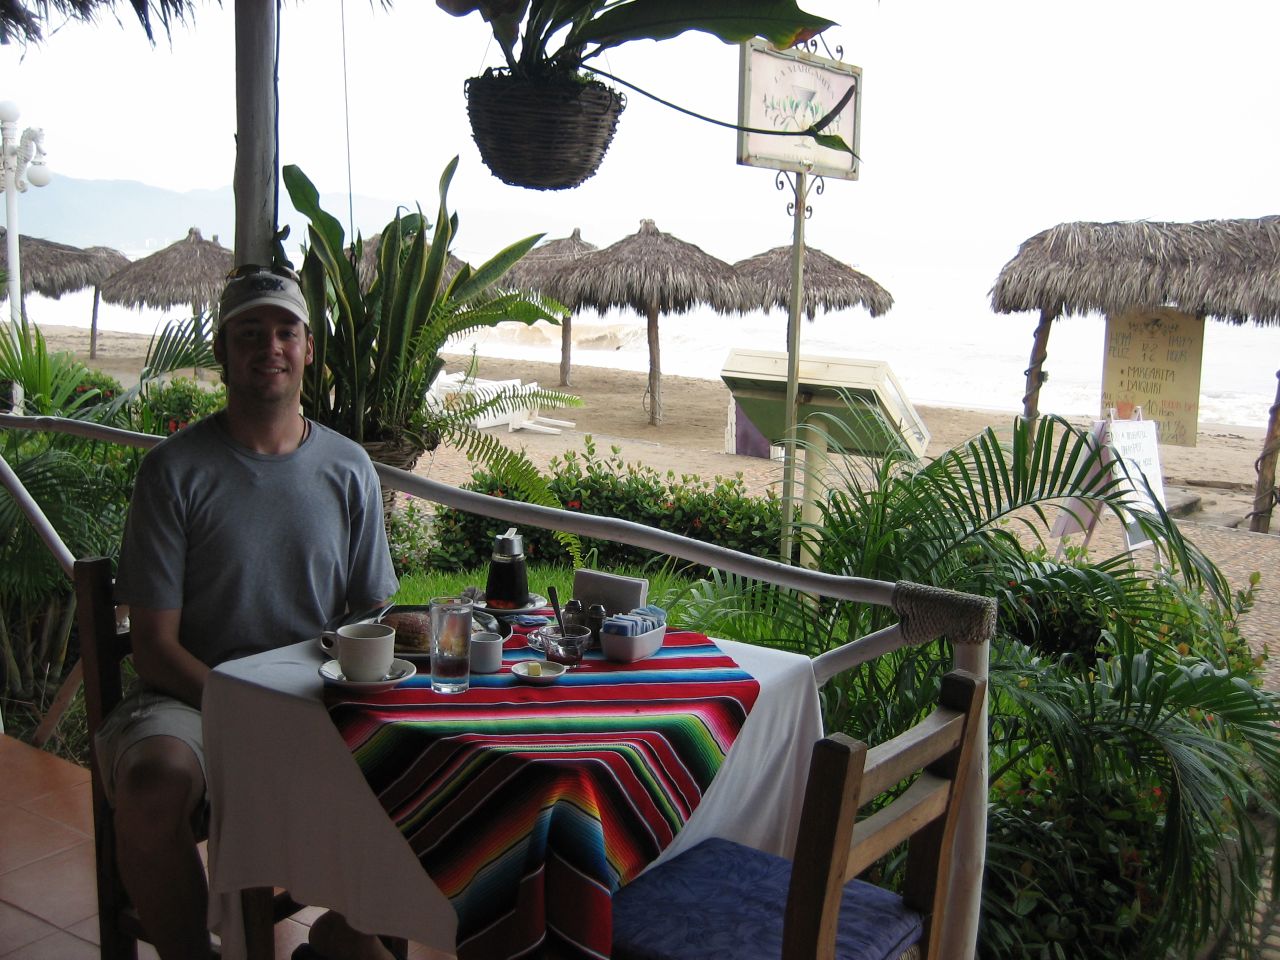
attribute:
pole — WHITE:
[762, 150, 827, 568]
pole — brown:
[767, 188, 821, 573]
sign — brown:
[739, 29, 868, 186]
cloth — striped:
[348, 596, 713, 958]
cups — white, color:
[328, 621, 408, 685]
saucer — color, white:
[319, 658, 423, 690]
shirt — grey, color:
[119, 429, 417, 690]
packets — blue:
[598, 598, 678, 636]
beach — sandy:
[4, 300, 1278, 676]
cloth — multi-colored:
[309, 588, 764, 950]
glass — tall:
[430, 603, 477, 701]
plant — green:
[450, 0, 892, 166]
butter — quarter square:
[525, 658, 541, 674]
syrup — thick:
[487, 554, 538, 612]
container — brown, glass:
[481, 526, 534, 608]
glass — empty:
[426, 587, 484, 705]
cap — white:
[220, 270, 322, 337]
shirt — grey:
[127, 411, 406, 690]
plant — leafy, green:
[436, 2, 838, 190]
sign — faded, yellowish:
[1101, 305, 1205, 447]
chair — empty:
[615, 665, 986, 957]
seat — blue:
[610, 835, 928, 957]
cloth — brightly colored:
[319, 629, 763, 954]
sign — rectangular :
[736, 38, 862, 176]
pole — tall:
[778, 172, 807, 565]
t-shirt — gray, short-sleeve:
[118, 409, 405, 699]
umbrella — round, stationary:
[710, 243, 894, 319]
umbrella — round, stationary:
[553, 217, 743, 423]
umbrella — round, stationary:
[487, 228, 604, 388]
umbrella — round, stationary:
[99, 230, 236, 379]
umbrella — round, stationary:
[81, 245, 132, 358]